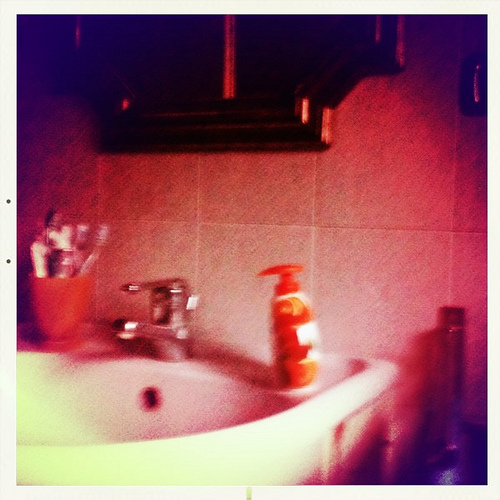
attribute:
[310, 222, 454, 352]
tile — white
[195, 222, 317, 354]
tile — white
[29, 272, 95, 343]
cup — red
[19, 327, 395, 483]
sink — white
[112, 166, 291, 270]
tile — white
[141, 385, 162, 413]
drain hole — small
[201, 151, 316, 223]
tile — white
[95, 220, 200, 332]
tile — white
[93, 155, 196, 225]
tile — white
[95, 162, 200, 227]
tile — white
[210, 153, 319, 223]
tile — white